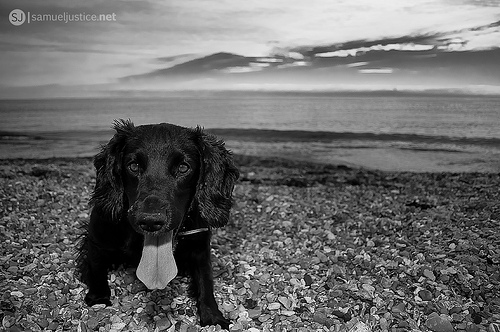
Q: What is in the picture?
A: A dog.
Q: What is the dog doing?
A: Sitting.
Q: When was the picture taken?
A: Daytime.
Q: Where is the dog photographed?
A: A river bank.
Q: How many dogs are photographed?
A: One.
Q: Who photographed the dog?
A: Pet owner.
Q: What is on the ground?
A: Rocks.